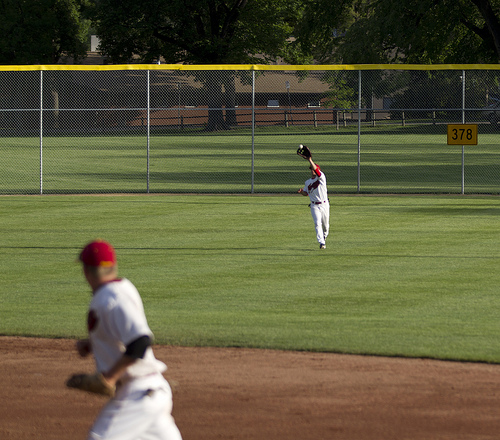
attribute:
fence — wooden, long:
[3, 100, 499, 133]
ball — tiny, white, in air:
[298, 141, 303, 151]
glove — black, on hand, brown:
[295, 145, 311, 160]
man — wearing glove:
[293, 154, 332, 250]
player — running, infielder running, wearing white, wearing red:
[65, 241, 181, 439]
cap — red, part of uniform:
[76, 241, 117, 265]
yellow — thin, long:
[1, 61, 498, 70]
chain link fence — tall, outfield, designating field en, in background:
[1, 66, 500, 199]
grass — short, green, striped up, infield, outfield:
[1, 119, 496, 363]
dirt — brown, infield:
[1, 334, 498, 439]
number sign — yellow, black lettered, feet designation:
[446, 123, 478, 146]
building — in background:
[11, 53, 348, 131]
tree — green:
[1, 4, 101, 137]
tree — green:
[94, 3, 304, 134]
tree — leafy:
[273, 2, 397, 128]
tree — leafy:
[339, 0, 497, 129]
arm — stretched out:
[308, 154, 321, 176]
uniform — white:
[305, 167, 332, 250]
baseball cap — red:
[309, 163, 320, 170]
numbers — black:
[450, 126, 475, 143]